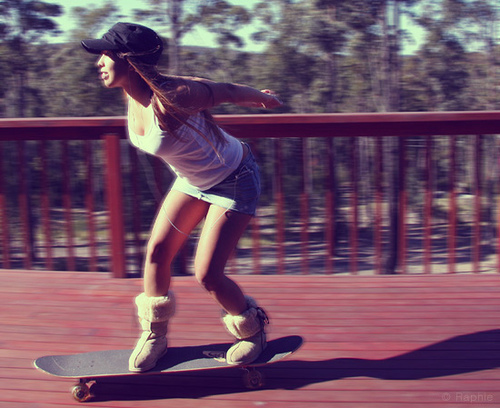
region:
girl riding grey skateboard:
[8, 0, 368, 405]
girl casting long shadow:
[35, 8, 489, 403]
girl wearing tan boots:
[96, 286, 298, 383]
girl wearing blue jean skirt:
[146, 140, 271, 227]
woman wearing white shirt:
[125, 79, 251, 204]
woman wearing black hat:
[69, 20, 170, 74]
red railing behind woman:
[3, 53, 499, 314]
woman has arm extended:
[83, 0, 309, 398]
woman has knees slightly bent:
[18, 8, 353, 405]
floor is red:
[2, 238, 496, 405]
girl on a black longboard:
[39, 22, 309, 391]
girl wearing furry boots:
[115, 280, 282, 374]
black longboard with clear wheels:
[40, 300, 325, 402]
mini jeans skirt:
[170, 147, 270, 225]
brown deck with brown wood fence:
[12, 97, 494, 397]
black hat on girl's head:
[64, 15, 172, 92]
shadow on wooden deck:
[81, 314, 498, 404]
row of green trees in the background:
[27, 15, 486, 160]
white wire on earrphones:
[120, 126, 245, 243]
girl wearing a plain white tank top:
[115, 82, 237, 199]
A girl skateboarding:
[72, 14, 299, 388]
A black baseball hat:
[68, 10, 173, 69]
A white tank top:
[113, 102, 267, 186]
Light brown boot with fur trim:
[118, 272, 280, 374]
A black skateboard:
[12, 310, 322, 405]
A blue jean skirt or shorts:
[172, 163, 269, 224]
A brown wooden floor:
[292, 261, 449, 394]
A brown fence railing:
[276, 85, 460, 234]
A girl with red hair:
[95, 55, 225, 126]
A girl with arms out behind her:
[62, 15, 287, 212]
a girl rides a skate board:
[61, 11, 323, 357]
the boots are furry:
[126, 286, 288, 392]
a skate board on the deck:
[25, 335, 367, 400]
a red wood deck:
[323, 288, 498, 396]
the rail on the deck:
[286, 98, 493, 294]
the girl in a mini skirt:
[160, 155, 287, 234]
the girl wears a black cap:
[67, 11, 163, 100]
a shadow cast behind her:
[315, 341, 467, 376]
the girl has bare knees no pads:
[131, 224, 243, 303]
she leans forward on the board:
[76, 16, 190, 190]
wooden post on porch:
[346, 132, 363, 280]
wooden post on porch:
[290, 140, 312, 274]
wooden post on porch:
[418, 135, 433, 273]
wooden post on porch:
[459, 136, 481, 275]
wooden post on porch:
[82, 141, 104, 272]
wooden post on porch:
[62, 144, 78, 272]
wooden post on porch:
[34, 132, 55, 266]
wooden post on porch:
[14, 130, 37, 265]